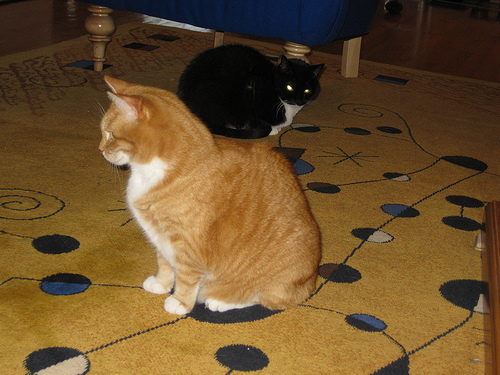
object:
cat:
[176, 43, 329, 140]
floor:
[0, 23, 498, 373]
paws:
[163, 294, 194, 315]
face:
[97, 102, 132, 166]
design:
[349, 226, 395, 244]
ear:
[106, 90, 154, 123]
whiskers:
[281, 104, 287, 119]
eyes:
[286, 84, 295, 92]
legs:
[82, 5, 117, 72]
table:
[80, 0, 379, 78]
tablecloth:
[73, 0, 373, 49]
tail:
[210, 126, 272, 139]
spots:
[120, 42, 160, 53]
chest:
[122, 177, 164, 218]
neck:
[283, 103, 305, 113]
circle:
[306, 182, 341, 194]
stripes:
[177, 276, 200, 286]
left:
[0, 0, 134, 375]